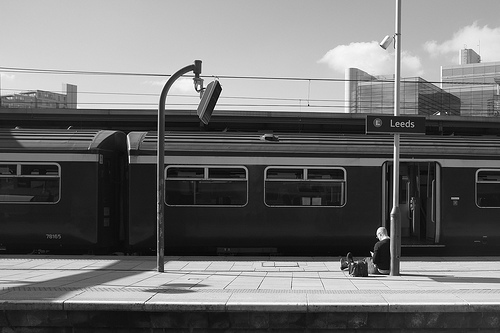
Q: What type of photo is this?
A: Black and white.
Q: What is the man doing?
A: Sitting.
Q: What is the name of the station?
A: Leeds.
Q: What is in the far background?
A: Buildings.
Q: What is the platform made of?
A: Cement.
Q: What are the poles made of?
A: Metal.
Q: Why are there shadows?
A: Sunny.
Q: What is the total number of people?
A: 1.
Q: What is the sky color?
A: Gray.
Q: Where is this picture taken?
A: A train station.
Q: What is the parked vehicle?
A: A passenger train.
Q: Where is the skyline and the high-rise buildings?
A: In the distance, beyond the train.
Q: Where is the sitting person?
A: Resting against the tall, metal post, with the sign that says "Leeds".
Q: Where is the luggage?
A: To the left of the seated person.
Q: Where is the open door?
A: On the train, across from the sign, and the person.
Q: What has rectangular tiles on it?
A: The train platform.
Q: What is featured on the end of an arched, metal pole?
A: A large, square security light.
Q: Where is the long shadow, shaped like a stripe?
A: Running across the platform, behind the arched pole.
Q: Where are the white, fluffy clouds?
A: In the sky.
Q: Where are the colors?
A: There are none, because it is a black and white photo.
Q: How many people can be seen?
A: One.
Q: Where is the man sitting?
A: On the ground.